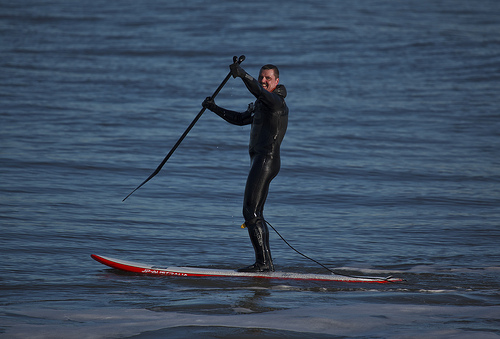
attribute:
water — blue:
[3, 5, 500, 333]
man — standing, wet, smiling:
[206, 44, 305, 271]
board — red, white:
[88, 247, 408, 288]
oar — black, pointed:
[115, 49, 250, 205]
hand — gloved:
[222, 47, 247, 81]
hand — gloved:
[200, 92, 217, 114]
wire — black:
[260, 213, 399, 281]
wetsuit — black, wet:
[219, 81, 290, 271]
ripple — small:
[320, 262, 496, 300]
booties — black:
[242, 235, 280, 275]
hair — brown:
[262, 63, 282, 76]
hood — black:
[274, 83, 290, 98]